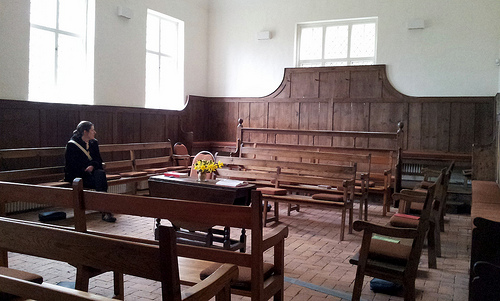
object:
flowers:
[193, 158, 224, 173]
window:
[27, 4, 94, 106]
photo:
[0, 0, 498, 301]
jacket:
[65, 134, 103, 170]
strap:
[67, 140, 92, 160]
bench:
[0, 138, 190, 223]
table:
[147, 171, 255, 207]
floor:
[0, 192, 472, 301]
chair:
[349, 166, 447, 300]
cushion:
[120, 171, 148, 177]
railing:
[236, 118, 410, 149]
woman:
[63, 120, 116, 223]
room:
[0, 11, 500, 266]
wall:
[209, 17, 500, 144]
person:
[63, 120, 116, 223]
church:
[0, 63, 500, 300]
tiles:
[285, 218, 333, 287]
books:
[370, 212, 419, 244]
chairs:
[347, 161, 455, 300]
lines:
[30, 23, 86, 41]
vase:
[197, 171, 208, 182]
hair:
[73, 120, 94, 138]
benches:
[183, 117, 405, 241]